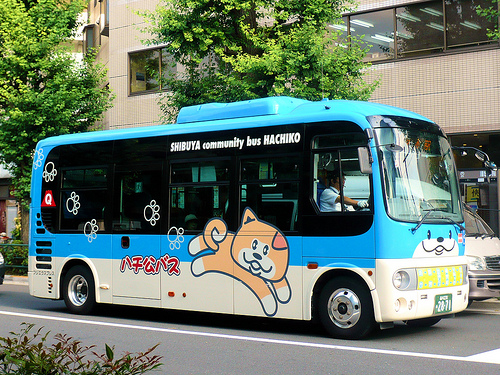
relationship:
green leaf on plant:
[24, 81, 48, 107] [1, 1, 117, 275]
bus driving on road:
[30, 96, 470, 339] [2, 285, 500, 374]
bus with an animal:
[30, 96, 470, 339] [185, 201, 295, 317]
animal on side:
[185, 201, 295, 317] [31, 117, 374, 321]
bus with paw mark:
[30, 96, 470, 339] [44, 161, 56, 183]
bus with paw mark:
[30, 96, 470, 339] [66, 194, 81, 214]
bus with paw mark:
[30, 96, 470, 339] [84, 220, 96, 242]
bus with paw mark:
[30, 96, 470, 339] [143, 201, 161, 226]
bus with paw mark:
[30, 96, 470, 339] [166, 227, 186, 252]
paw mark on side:
[44, 161, 56, 183] [31, 117, 374, 321]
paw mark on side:
[66, 194, 81, 214] [31, 117, 374, 321]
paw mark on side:
[84, 220, 96, 242] [31, 117, 374, 321]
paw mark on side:
[143, 201, 161, 226] [31, 117, 374, 321]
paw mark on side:
[166, 227, 186, 252] [31, 117, 374, 321]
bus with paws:
[30, 96, 470, 339] [264, 293, 275, 313]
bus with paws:
[30, 96, 470, 339] [274, 285, 293, 301]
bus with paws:
[30, 96, 470, 339] [192, 256, 205, 274]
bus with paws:
[30, 96, 470, 339] [191, 235, 196, 254]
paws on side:
[264, 293, 275, 313] [31, 117, 374, 321]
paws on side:
[274, 285, 293, 301] [31, 117, 374, 321]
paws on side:
[192, 256, 205, 274] [31, 117, 374, 321]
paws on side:
[191, 235, 196, 254] [31, 117, 374, 321]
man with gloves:
[324, 163, 372, 219] [353, 190, 369, 210]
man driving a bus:
[324, 163, 372, 219] [18, 109, 467, 307]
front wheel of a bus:
[316, 273, 376, 338] [30, 96, 470, 339]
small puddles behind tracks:
[114, 178, 136, 251] [138, 188, 185, 252]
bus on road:
[30, 96, 470, 339] [2, 275, 498, 371]